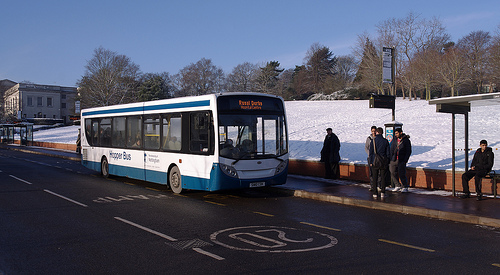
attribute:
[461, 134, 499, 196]
man — wearing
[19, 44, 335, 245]
bus — public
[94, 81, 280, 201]
bus — blue and white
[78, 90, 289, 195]
bus — white , blue 